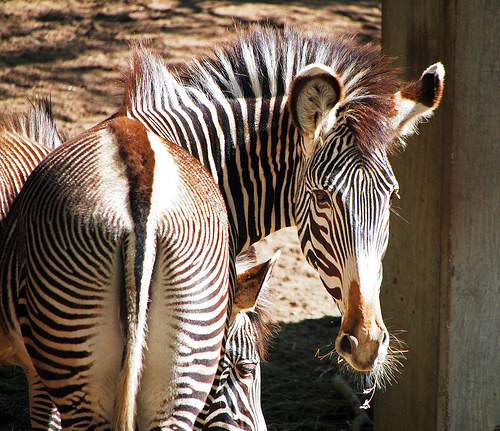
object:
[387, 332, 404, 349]
whiskers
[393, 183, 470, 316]
enclosure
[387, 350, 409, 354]
whiskers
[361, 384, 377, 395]
twig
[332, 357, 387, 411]
mouth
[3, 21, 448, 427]
zebra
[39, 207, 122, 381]
zebra's butt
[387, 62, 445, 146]
ear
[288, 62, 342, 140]
ear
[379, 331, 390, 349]
nostril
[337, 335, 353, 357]
nostril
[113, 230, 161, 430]
tail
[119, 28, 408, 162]
mane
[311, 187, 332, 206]
eye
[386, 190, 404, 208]
eye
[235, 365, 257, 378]
eye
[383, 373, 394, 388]
whiskers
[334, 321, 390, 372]
snout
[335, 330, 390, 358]
nose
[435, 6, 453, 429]
post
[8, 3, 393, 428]
ground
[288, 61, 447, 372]
head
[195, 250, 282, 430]
head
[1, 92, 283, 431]
zebra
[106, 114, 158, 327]
stripe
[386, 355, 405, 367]
whiskers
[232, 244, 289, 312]
ear